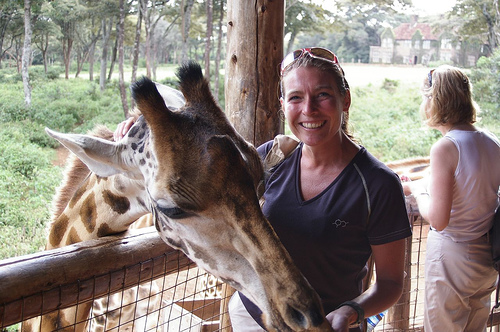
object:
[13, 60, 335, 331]
giraffe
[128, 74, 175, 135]
horn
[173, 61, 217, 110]
horn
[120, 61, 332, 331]
head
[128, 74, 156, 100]
hair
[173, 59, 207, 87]
hair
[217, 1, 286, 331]
post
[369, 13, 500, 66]
building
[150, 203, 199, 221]
eye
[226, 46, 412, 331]
woman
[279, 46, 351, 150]
head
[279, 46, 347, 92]
sunglasses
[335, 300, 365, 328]
watch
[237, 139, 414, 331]
shirt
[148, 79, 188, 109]
ear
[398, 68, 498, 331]
woman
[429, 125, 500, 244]
shirt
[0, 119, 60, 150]
bushes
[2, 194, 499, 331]
fence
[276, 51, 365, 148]
hair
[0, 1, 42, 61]
trees